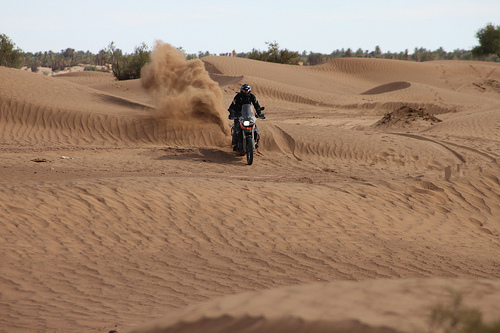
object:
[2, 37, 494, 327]
sand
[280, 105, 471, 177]
sandbank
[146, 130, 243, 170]
shadow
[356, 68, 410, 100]
spot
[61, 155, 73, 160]
whitish object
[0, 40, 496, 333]
dune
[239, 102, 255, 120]
windshield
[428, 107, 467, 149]
ground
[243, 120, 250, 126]
headlight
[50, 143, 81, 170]
object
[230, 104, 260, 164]
bike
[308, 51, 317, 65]
trees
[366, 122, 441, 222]
prints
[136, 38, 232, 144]
air-kicked sand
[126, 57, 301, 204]
dirt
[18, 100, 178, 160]
bank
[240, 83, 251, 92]
helmet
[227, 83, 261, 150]
biker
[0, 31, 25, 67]
tree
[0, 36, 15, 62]
green leaves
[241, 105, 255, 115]
screen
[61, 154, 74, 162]
object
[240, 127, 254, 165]
tire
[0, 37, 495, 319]
beach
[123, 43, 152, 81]
trees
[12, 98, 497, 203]
patch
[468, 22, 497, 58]
tree